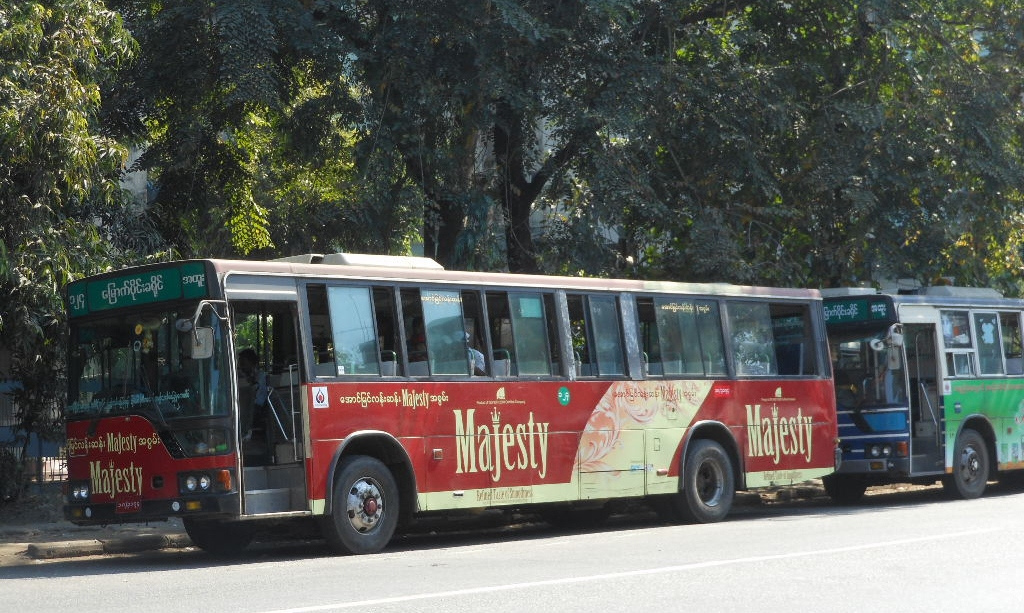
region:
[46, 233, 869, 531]
a large red and white bus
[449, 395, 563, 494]
Majesty on the side of the bus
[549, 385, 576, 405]
a green round circle on the side of the bus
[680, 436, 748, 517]
a back tire without a hub cap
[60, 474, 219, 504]
four head lights on the front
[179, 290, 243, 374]
a mirror to the side and front of the bus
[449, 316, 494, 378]
one passenger seen through the open window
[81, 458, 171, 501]
Majesty on the front of the bus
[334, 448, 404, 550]
a tire on the bus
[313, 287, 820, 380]
windows on the bus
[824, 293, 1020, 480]
a large green bus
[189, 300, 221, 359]
the side mirror on the bus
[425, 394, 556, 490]
Majesty logo on a bus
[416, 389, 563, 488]
Majesty logo on a bus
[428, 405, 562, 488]
Majesty logo on a bus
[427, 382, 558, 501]
Majesty logo on a bus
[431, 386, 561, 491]
Majesty logo on a bus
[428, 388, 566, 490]
Majesty logo on a bus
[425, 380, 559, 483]
Majesty logo on a bus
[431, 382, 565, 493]
Majesty logo on a bus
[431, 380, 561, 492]
Majesty logo on a bus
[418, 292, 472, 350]
window of passenger bus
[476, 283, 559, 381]
window of passenger bus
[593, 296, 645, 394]
window of passenger bus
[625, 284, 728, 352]
window of passenger bus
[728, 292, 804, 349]
window of passenger bus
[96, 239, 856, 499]
red passenger bus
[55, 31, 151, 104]
green leaves in brown trees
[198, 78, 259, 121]
green leaves in brown trees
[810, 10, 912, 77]
green leaves in brown trees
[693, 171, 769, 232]
green leaves in brown trees